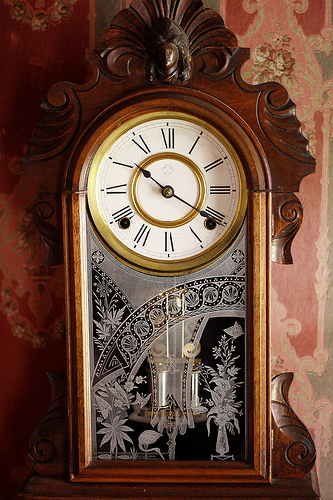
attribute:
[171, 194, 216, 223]
hand — black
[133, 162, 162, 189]
hand — black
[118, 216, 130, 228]
key slot — winding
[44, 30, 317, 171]
carving — wooden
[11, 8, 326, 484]
wall — ornate, red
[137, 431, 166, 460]
bird — white, downward-looking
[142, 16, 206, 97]
face — decorative, carving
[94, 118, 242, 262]
face — white, clock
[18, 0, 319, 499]
clock — mantle, antique, intricately carved, brown, wooden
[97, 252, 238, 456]
design — white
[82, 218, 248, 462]
panel — glass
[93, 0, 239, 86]
carving — wood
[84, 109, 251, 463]
clock — display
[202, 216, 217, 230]
keyhole — time-setter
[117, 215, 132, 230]
keyhole — time-setter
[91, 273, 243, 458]
design — white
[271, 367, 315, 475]
carving — intricate